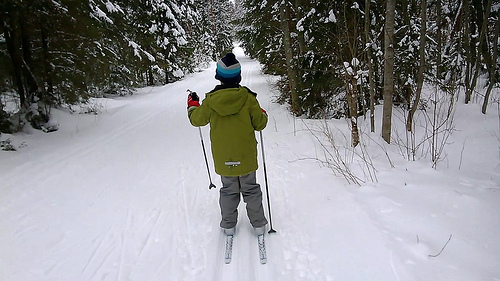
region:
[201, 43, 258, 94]
Person wearing a winter hat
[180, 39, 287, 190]
Person wearing a winter coat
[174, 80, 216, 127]
Person wearing a red glove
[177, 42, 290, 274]
Boy Skiing in the snow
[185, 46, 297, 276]
Person wearing grey pants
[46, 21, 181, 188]
Trees in the forest after a snow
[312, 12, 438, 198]
Trees in the snow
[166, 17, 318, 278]
Boy skiing down a trail in the woods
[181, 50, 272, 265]
young person on snow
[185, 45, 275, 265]
young person skiing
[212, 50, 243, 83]
blue and white beanie on the young skier's head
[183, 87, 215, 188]
black ski pole in the young person's hand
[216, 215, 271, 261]
skis on the young person's feet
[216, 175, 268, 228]
gray pants on the skier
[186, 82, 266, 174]
an olive green coat on the young skier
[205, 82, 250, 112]
olive colored hood on the young person's coat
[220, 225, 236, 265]
ski on the young man's foot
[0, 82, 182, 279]
lots of ski tracks in the snow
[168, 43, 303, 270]
small child cross country skiing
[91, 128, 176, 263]
fresh snow on a trail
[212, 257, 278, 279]
cross country ski tracks on a trail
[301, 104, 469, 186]
small twigs in the snow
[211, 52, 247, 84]
blue and grey knit hat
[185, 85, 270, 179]
pea green winter jacket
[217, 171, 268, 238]
grey snow pants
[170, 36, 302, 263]
young boy cross country skiing on trail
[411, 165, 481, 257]
untouched snow on the side of a trail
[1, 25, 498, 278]
The ground is covered in snow.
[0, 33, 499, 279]
The snow is white.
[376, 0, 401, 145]
The tree trunk is straight.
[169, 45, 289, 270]
The boy is holding ski poles.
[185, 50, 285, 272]
The boy is wearing skis.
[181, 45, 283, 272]
The boy is wearing pants.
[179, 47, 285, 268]
The boy is wearing a jacket.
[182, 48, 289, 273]
The boy is wearing a cap.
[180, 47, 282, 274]
The boy's pants are gray.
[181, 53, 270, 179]
The jacket is green.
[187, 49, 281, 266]
The kid wearing skates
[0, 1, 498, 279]
The snow filled road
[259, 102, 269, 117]
The partially hidden red gloves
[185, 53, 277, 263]
The child wearing a green jersey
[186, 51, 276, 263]
The kid wearing gray pants and a hoodie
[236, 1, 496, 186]
The snow filled bushes on the right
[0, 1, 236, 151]
The snow filled bushes on the left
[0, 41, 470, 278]
The long snow filled passage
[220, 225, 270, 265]
The duo gray skates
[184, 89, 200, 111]
The red protective gloves on the left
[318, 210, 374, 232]
the snow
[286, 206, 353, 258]
the snow is white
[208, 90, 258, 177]
a green jacket the person is wearing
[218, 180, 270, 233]
grey pants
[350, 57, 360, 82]
green leaves on the tree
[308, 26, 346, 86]
green leaves on the tree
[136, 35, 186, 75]
green leaves on the tree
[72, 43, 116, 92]
green leaves on the tree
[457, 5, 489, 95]
green leaves on the tree